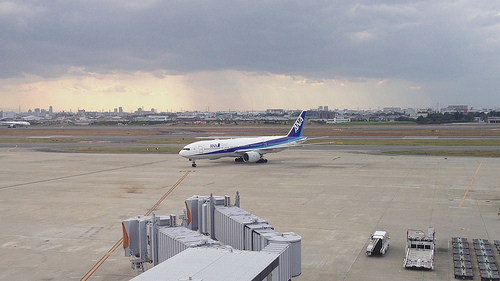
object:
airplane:
[0, 121, 33, 129]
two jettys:
[119, 191, 303, 281]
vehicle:
[364, 230, 390, 257]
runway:
[301, 142, 500, 152]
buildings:
[49, 105, 53, 116]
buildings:
[41, 108, 47, 115]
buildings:
[34, 108, 40, 116]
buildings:
[118, 107, 123, 114]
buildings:
[113, 108, 118, 113]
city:
[326, 104, 500, 127]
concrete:
[0, 163, 500, 217]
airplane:
[177, 110, 309, 167]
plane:
[177, 110, 309, 168]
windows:
[178, 144, 201, 158]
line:
[456, 160, 484, 209]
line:
[81, 167, 192, 279]